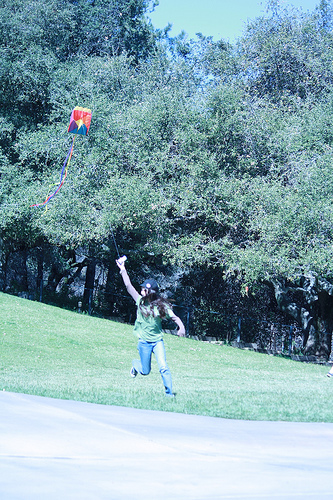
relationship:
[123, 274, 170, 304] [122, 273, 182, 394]
head of girl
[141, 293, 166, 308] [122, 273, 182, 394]
hair of girl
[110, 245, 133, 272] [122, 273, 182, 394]
hand of girl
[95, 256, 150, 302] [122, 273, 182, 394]
arm of girl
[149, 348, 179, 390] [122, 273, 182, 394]
leg of girl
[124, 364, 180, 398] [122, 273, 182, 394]
foot of girl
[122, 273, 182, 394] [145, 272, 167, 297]
girl wearing hat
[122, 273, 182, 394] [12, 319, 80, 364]
girl on grass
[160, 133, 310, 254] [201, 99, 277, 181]
trees with leaves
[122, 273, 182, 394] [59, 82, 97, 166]
girl flying kite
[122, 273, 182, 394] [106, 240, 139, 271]
girl holding handle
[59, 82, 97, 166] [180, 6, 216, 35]
kite in air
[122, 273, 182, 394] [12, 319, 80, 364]
girl running on grass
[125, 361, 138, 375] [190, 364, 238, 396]
back foot lifted off ground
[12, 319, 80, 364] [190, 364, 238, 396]
green grass on ground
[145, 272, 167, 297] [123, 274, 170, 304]
hat on head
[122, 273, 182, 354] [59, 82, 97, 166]
girl flying kite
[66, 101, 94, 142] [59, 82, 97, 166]
red, blue, yellow on kite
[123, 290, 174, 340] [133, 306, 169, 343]
wrinkles on shirt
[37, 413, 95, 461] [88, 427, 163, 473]
patch of black asphalt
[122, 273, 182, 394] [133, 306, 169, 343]
girl wearing green t-shirt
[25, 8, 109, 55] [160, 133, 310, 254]
dark green trees